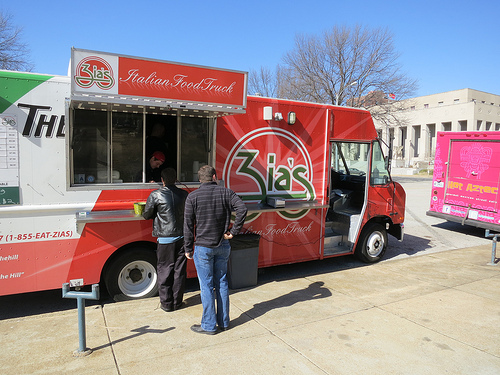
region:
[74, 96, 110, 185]
window on food truck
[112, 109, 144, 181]
window on food truck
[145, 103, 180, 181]
window on food truck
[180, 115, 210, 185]
window on food truck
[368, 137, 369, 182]
window on food truck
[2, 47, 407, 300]
food truck is red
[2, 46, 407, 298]
red truck is parked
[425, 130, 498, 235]
parked truck is pink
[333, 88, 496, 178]
building behind parked truck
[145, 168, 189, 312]
person ordering at food truck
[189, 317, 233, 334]
Man wearing shoes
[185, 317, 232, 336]
Man is wearing shoes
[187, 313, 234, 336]
Man wearing black shoes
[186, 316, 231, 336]
Man is wearing black shoes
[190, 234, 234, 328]
Man wearing pants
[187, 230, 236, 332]
Man is wearing pants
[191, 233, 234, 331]
Man wearing blue pants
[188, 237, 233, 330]
Man is wearing blue pants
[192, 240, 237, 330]
Man wearing blue jeans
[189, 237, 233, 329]
Man is wearing blue jeans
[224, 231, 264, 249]
a black trash bag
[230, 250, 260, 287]
a tall gray trashcan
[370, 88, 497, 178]
part of a brown building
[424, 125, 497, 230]
part of a pink and gray truck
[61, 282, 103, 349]
a blue pole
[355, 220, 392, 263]
a black truck tire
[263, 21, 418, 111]
part of a large tree with no leaves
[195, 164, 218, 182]
a man's short cut hair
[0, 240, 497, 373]
part of a sidewalk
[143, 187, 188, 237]
part of a black leather jacket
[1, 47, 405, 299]
the food truck on the side of the road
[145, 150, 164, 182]
the man in the food truck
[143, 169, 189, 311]
the man making an order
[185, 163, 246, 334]
the man standing in line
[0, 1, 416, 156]
the bare trees in the back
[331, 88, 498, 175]
the building near the tree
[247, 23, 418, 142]
the trees near the building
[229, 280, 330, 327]
the man's shadow on the ground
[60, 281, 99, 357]
the metal piece on the sidewalk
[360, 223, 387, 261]
the wheel on the food truck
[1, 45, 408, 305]
A red, white and green food truck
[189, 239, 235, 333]
A pair of blue jeans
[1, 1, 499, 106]
The sky is clear and blue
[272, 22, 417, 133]
A tree with no leaves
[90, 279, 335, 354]
Shadows on the sidewalk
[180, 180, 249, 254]
Stripes on a long sleeved black shirt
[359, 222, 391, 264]
A black round tire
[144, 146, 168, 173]
Red hat on person's head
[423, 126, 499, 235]
Back of a pink truck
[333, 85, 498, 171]
A large white building